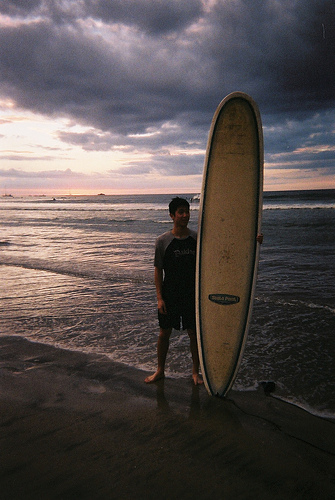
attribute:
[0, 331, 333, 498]
sand — beach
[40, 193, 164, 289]
water — white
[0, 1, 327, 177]
clouds — dark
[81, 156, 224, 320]
boy — light skinned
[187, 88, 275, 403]
board — white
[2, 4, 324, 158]
cloud — dark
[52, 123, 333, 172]
cloud — dark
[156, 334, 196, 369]
legs — short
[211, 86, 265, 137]
top — sharp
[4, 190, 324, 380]
water — ocean